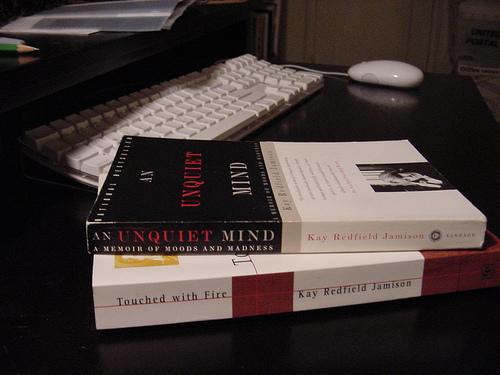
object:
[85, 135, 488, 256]
book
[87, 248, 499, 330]
book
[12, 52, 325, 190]
keyboard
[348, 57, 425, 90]
mouse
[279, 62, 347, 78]
wire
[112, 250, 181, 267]
mark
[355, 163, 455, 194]
photo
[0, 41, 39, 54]
pencil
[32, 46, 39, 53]
lead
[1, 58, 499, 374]
desk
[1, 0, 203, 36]
paper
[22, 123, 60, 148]
button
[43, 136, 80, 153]
button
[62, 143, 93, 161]
button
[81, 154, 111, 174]
button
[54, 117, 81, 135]
button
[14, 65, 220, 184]
shadow